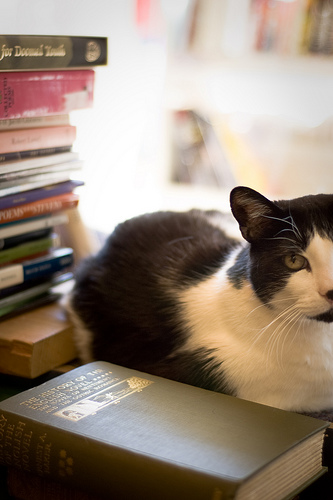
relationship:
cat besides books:
[64, 176, 331, 422] [1, 33, 84, 378]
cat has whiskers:
[64, 176, 331, 422] [244, 294, 313, 362]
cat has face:
[64, 184, 330, 422] [255, 196, 331, 321]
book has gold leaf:
[0, 34, 109, 319] [122, 374, 149, 388]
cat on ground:
[64, 176, 331, 422] [273, 96, 286, 110]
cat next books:
[64, 184, 330, 422] [1, 26, 111, 343]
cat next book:
[64, 176, 331, 422] [0, 359, 332, 498]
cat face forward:
[64, 184, 330, 422] [4, 152, 331, 495]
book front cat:
[0, 34, 109, 319] [64, 176, 331, 422]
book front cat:
[1, 71, 95, 116] [64, 176, 331, 422]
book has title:
[48, 359, 332, 483] [33, 360, 145, 445]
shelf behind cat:
[173, 18, 326, 61] [64, 176, 331, 422]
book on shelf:
[0, 34, 109, 319] [0, 375, 33, 391]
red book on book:
[1, 65, 97, 119] [0, 34, 109, 319]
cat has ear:
[64, 176, 331, 422] [223, 185, 287, 240]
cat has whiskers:
[64, 184, 330, 422] [251, 294, 305, 343]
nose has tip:
[322, 281, 331, 301] [326, 287, 331, 297]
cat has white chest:
[64, 176, 331, 422] [167, 275, 332, 412]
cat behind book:
[64, 176, 331, 422] [0, 359, 332, 498]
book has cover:
[0, 360, 331, 499] [3, 357, 331, 477]